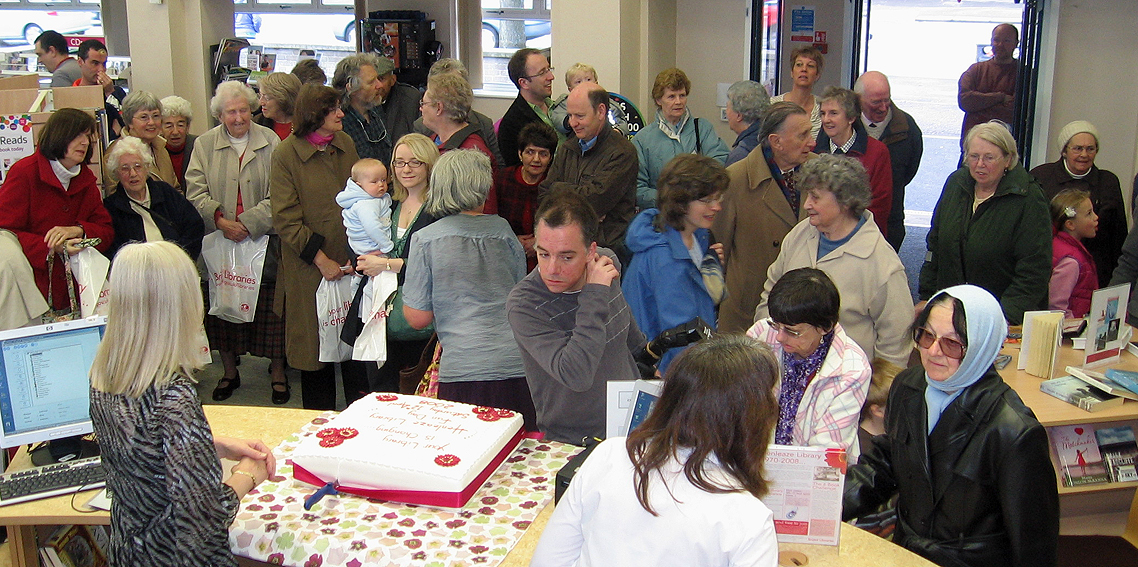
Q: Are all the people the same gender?
A: No, they are both male and female.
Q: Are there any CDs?
A: No, there are no cds.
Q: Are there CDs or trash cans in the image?
A: No, there are no CDs or trash cans.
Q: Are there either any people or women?
A: Yes, there is a woman.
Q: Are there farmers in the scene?
A: No, there are no farmers.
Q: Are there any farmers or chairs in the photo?
A: No, there are no farmers or chairs.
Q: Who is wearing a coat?
A: The woman is wearing a coat.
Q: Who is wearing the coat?
A: The woman is wearing a coat.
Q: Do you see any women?
A: Yes, there is a woman.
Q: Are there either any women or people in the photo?
A: Yes, there is a woman.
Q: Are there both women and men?
A: Yes, there are both a woman and a man.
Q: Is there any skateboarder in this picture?
A: No, there are no skateboarders.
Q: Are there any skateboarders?
A: No, there are no skateboarders.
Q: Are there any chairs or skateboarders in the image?
A: No, there are no skateboarders or chairs.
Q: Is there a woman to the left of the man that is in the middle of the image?
A: Yes, there is a woman to the left of the man.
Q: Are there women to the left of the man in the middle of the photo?
A: Yes, there is a woman to the left of the man.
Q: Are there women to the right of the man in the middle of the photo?
A: No, the woman is to the left of the man.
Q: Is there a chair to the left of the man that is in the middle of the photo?
A: No, there is a woman to the left of the man.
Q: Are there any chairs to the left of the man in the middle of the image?
A: No, there is a woman to the left of the man.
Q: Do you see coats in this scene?
A: Yes, there is a coat.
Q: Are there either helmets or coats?
A: Yes, there is a coat.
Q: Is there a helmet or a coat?
A: Yes, there is a coat.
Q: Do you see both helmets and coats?
A: No, there is a coat but no helmets.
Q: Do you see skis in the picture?
A: No, there are no skis.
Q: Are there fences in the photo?
A: No, there are no fences.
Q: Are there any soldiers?
A: No, there are no soldiers.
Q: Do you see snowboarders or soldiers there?
A: No, there are no soldiers or snowboarders.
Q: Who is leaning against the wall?
A: The man is leaning against the wall.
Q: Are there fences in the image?
A: No, there are no fences.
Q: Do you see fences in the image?
A: No, there are no fences.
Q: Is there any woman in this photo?
A: Yes, there is a woman.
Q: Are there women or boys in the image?
A: Yes, there is a woman.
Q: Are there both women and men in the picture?
A: Yes, there are both a woman and a man.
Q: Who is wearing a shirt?
A: The woman is wearing a shirt.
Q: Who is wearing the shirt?
A: The woman is wearing a shirt.